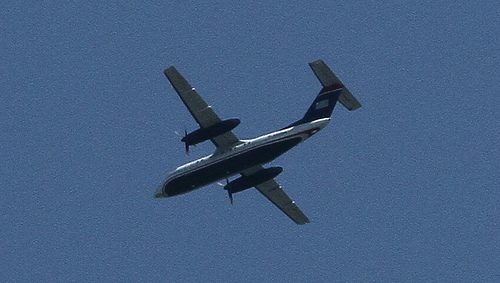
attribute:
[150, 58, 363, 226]
plane — blue, white, black, silver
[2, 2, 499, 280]
blue sky — clear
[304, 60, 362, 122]
verticle stabilizer — blue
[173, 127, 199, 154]
propellor — small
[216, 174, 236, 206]
propellor — small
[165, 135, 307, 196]
belly — black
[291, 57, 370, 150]
tail — white, blue, silver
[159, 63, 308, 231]
wings — long, white